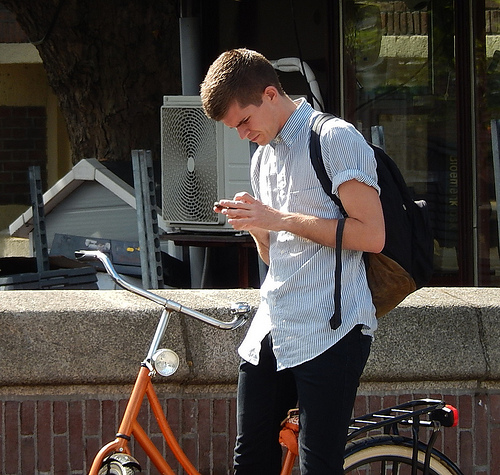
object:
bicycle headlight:
[150, 346, 182, 378]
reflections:
[340, 6, 477, 291]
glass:
[338, 0, 471, 286]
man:
[197, 45, 386, 474]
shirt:
[235, 98, 380, 375]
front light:
[150, 348, 180, 376]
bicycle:
[58, 242, 470, 474]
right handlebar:
[71, 245, 135, 288]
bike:
[65, 246, 464, 474]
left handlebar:
[191, 297, 256, 334]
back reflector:
[430, 403, 460, 427]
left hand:
[215, 193, 274, 238]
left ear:
[264, 84, 280, 107]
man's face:
[215, 92, 280, 152]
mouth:
[248, 129, 261, 148]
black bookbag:
[307, 110, 436, 307]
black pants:
[229, 323, 372, 474]